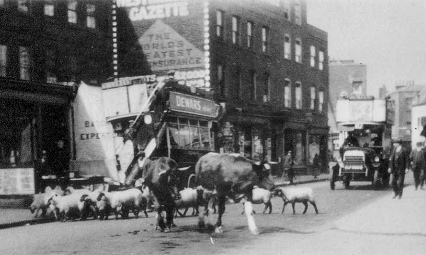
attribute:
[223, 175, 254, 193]
chest — part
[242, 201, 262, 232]
hoof — part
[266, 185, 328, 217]
sheep — black, white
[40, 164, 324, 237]
animals — grouping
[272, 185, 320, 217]
sheep — walking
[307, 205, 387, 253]
line — part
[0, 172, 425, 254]
road — part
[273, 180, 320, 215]
sheep — herd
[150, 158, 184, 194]
head — slightly bent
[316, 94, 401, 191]
car — driving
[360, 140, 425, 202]
man — standing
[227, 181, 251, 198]
chest — part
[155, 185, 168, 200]
chest — part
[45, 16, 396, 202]
building — edge